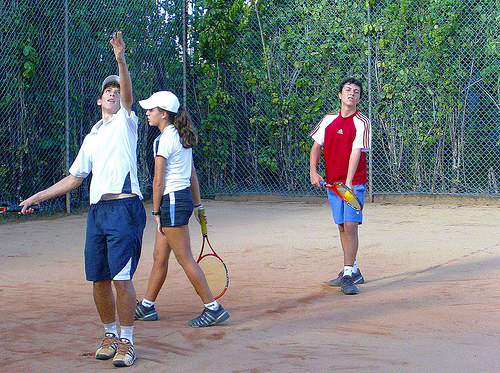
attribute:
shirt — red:
[307, 111, 371, 186]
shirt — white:
[68, 99, 143, 201]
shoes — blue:
[327, 264, 369, 299]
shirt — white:
[146, 127, 210, 204]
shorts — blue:
[308, 158, 393, 233]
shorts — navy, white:
[76, 195, 148, 285]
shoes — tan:
[94, 329, 136, 369]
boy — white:
[301, 73, 379, 303]